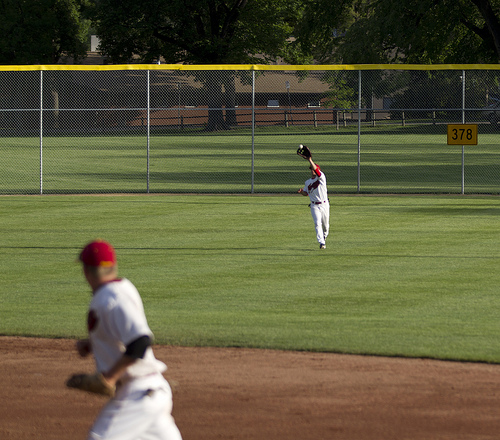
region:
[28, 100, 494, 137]
a long wooden fence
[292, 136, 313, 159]
a ball in a black glove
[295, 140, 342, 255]
a man catching a ball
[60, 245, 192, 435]
a man running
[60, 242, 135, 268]
a red cap on a man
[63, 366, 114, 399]
a glove on a hand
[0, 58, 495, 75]
yellow on a fence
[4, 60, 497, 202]
a tall chain link fence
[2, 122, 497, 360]
short green grass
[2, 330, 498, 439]
dirt in a baseball diamond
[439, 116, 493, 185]
number sign on outfield fence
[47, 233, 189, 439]
baseball player throwing ball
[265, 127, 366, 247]
baseball player catching ball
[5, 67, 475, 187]
outfield baseball field fence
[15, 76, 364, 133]
building on outside of baseballfield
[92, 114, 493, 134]
fence surrounding building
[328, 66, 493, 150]
set of trees in field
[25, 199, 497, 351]
striped up grass field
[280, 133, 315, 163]
baseball glove with baseball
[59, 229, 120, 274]
red baseball hat for uniform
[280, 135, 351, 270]
outfielder catching the ball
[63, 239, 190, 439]
male infielder running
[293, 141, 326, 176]
arm stretched out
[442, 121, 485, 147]
yellow sign with black lettering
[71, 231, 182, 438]
white uniform and red baseball cap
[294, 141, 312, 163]
tiny white ball heading for the brown baseball glove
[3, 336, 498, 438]
brown dirt on the infield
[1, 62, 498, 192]
fence designating end of the field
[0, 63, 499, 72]
thin and long yellow strip on the top of the fence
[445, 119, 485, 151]
sign telling how many feet away the fence is from home plate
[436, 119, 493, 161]
A yellow sign.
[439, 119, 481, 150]
The sign has black numbers.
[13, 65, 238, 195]
A fence is in the background.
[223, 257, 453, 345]
The grass is green.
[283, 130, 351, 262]
The player is catching a ball.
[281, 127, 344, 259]
The player is wearing red and white.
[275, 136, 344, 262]
The player is wearing a mitt.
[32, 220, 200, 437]
The player is wearing a red hat.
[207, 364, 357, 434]
The dirt is brown.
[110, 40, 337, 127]
Buildings are in the background.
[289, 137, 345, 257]
an outfielder catching a fly ball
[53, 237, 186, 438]
an infielder turning his head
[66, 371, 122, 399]
the mitt on a infielder's hand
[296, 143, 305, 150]
the baseball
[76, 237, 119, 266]
the baseball player's baseball cap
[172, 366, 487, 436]
the infield of a baseball diamond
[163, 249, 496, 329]
the outfield of a baseball diamond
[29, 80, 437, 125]
a fence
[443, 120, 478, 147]
a 378 field marker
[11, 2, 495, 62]
leafy green trees